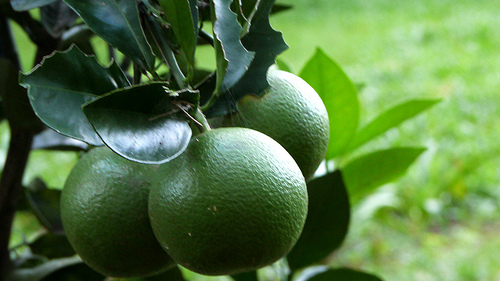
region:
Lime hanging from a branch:
[147, 126, 310, 272]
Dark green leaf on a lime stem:
[78, 76, 195, 166]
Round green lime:
[145, 122, 313, 279]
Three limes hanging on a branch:
[60, 64, 327, 279]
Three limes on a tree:
[57, 63, 329, 276]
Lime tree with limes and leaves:
[0, 0, 374, 280]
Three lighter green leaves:
[297, 45, 444, 211]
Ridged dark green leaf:
[12, 41, 129, 147]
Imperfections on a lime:
[180, 201, 221, 241]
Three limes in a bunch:
[57, 65, 333, 279]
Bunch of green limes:
[61, 60, 328, 279]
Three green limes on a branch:
[57, 61, 329, 279]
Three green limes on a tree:
[60, 69, 331, 279]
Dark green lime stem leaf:
[81, 77, 191, 163]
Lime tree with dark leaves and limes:
[0, 2, 368, 279]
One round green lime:
[144, 125, 311, 278]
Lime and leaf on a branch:
[81, 78, 310, 276]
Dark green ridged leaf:
[17, 41, 134, 148]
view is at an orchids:
[93, 41, 423, 253]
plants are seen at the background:
[375, 52, 462, 249]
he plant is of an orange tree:
[27, 2, 356, 280]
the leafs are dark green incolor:
[81, 74, 166, 140]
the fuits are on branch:
[74, 72, 317, 261]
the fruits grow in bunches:
[119, 72, 336, 277]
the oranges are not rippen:
[91, 132, 337, 257]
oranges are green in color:
[73, 116, 363, 274]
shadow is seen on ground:
[313, 172, 393, 279]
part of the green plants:
[363, 73, 418, 163]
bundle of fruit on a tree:
[64, 59, 336, 264]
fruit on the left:
[67, 145, 167, 262]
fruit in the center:
[157, 134, 285, 267]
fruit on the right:
[231, 53, 363, 162]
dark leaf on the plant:
[103, 79, 206, 159]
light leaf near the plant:
[309, 40, 370, 147]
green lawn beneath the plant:
[316, 20, 498, 222]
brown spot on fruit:
[208, 197, 217, 217]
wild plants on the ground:
[433, 140, 482, 198]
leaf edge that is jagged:
[40, 42, 94, 64]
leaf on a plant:
[16, 48, 122, 149]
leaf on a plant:
[85, 78, 201, 168]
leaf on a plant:
[281, 163, 348, 268]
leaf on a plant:
[334, 140, 415, 202]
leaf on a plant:
[341, 81, 443, 153]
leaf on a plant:
[293, 43, 358, 148]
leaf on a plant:
[305, 260, 380, 280]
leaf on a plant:
[200, 2, 256, 113]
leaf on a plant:
[230, 1, 288, 122]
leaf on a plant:
[66, 3, 161, 79]